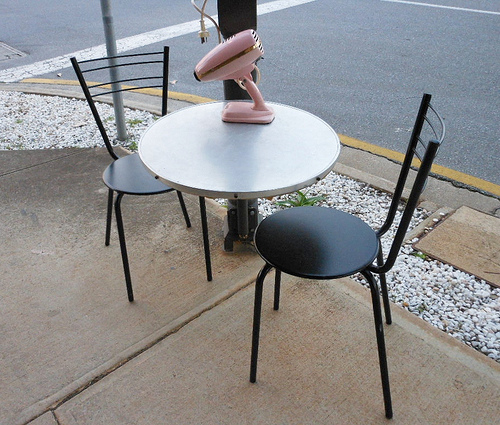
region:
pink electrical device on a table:
[191, 26, 278, 126]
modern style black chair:
[228, 88, 445, 420]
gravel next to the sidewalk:
[3, 89, 498, 366]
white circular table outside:
[136, 90, 343, 210]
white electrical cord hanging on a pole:
[183, 2, 228, 41]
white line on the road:
[2, 3, 358, 85]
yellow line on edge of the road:
[9, 67, 499, 224]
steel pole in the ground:
[94, 1, 135, 141]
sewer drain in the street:
[402, 188, 499, 307]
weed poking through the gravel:
[279, 191, 333, 211]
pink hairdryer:
[185, 28, 285, 123]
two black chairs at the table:
[68, 40, 430, 414]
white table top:
[143, 95, 335, 192]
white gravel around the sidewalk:
[2, 87, 499, 377]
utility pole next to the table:
[213, 3, 270, 261]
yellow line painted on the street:
[55, 71, 486, 206]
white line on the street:
[0, 11, 350, 120]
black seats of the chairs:
[104, 144, 369, 273]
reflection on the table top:
[200, 116, 283, 183]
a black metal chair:
[245, 85, 452, 417]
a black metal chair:
[65, 45, 223, 300]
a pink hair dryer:
[191, 25, 279, 128]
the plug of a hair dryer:
[195, 13, 212, 45]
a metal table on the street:
[135, 103, 341, 208]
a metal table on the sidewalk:
[133, 95, 341, 202]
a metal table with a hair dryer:
[135, 27, 349, 204]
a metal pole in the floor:
[95, 0, 133, 142]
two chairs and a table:
[53, 40, 447, 419]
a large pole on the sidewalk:
[215, 3, 263, 253]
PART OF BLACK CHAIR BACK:
[402, 80, 453, 189]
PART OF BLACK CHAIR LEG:
[364, 281, 399, 423]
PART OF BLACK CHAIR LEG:
[249, 277, 265, 383]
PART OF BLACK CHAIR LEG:
[382, 276, 402, 325]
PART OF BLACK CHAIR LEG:
[272, 274, 292, 317]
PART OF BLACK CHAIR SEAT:
[287, 234, 339, 272]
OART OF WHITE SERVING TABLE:
[227, 143, 279, 180]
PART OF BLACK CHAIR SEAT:
[113, 170, 145, 187]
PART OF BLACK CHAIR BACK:
[78, 56, 142, 98]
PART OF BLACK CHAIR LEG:
[116, 208, 151, 310]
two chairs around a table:
[58, 21, 450, 422]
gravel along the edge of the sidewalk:
[0, 84, 492, 385]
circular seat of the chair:
[246, 198, 378, 281]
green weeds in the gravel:
[276, 185, 330, 212]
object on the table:
[190, 33, 290, 129]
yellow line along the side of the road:
[19, 74, 496, 195]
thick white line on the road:
[0, 0, 322, 82]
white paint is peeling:
[4, 40, 105, 80]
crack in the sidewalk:
[19, 251, 287, 421]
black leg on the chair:
[244, 255, 269, 395]